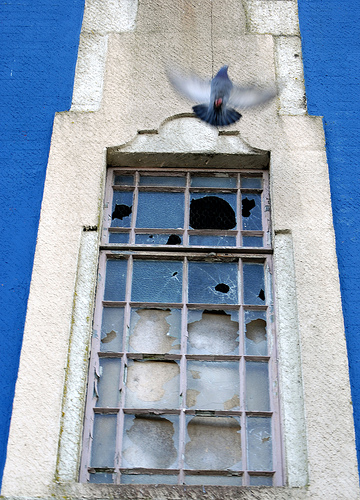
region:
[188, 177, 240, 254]
A broken window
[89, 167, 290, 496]
Most of the window panes are broken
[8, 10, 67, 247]
A blue section of the building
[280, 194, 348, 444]
A white section of the building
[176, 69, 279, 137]
A blue and white bird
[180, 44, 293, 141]
The bird is flying away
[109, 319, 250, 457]
Stone behind the window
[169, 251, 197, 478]
Wooden window trim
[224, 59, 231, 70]
Small beak of the bird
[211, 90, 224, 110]
The bird has orange feet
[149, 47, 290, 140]
a blue bird in flight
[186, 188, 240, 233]
a broken window pane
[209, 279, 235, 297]
a rock hole in glass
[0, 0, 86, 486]
a blue painted wall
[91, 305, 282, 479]
a boad behind broken window glass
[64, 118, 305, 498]
white framing around a window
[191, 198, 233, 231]
a dark room behind a window pane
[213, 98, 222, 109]
feet on a bird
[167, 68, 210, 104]
the white underside of a wing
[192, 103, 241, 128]
blue tail feathers on a bird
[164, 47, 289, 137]
bird flying in the air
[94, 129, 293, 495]
window in a building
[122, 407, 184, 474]
broken pane in the window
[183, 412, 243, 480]
broken pane in the window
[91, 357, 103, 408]
peeling paint on the window frame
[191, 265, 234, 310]
broken pane in the window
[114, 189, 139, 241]
broken pane in the window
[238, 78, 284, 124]
wing on the bird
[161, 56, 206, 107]
wing on the bird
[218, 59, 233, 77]
head of the bird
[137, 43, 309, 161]
Bird in the air.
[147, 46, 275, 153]
Bird by a building.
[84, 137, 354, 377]
Window on the building.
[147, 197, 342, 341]
Hole in the window.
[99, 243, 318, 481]
panes of glass on the building.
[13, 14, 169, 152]
Blue sky behind the building.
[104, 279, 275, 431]
Lines on the window.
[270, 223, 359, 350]
Cement building with windows.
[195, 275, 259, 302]
Bullet hole in the window.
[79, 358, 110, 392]
Chipped paint on the frame.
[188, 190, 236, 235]
black hole in the glass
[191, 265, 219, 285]
long, thin crack in the glass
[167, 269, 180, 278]
small hole in the glass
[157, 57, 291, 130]
bird flying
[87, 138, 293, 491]
window with frosted glass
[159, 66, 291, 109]
two white outstretched wings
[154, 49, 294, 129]
blue and white bird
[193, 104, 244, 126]
black and blue tail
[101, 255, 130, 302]
patch of glass that is not broken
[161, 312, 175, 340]
jagged piece of broken glass